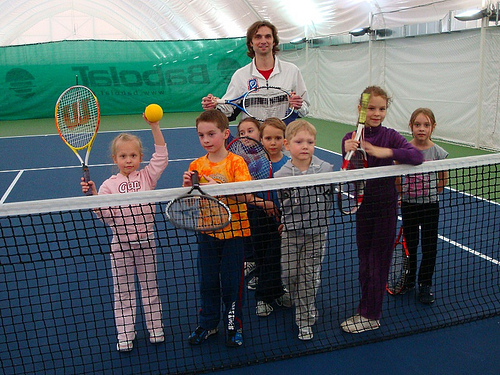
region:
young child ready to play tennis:
[93, 128, 168, 334]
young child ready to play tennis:
[181, 114, 251, 319]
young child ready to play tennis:
[235, 116, 257, 153]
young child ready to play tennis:
[257, 118, 286, 155]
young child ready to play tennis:
[281, 122, 343, 336]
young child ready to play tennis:
[345, 91, 402, 321]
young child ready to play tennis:
[404, 96, 458, 308]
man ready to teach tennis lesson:
[221, 21, 306, 115]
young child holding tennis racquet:
[39, 67, 106, 169]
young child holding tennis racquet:
[170, 183, 234, 243]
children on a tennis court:
[49, 82, 486, 349]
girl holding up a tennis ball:
[49, 85, 170, 190]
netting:
[0, 180, 498, 372]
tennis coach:
[198, 17, 317, 104]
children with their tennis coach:
[51, 17, 450, 355]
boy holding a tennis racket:
[170, 115, 263, 355]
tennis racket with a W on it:
[50, 77, 100, 187]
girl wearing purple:
[343, 78, 419, 336]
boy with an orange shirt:
[181, 106, 253, 244]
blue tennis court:
[0, 129, 492, 373]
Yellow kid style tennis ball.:
[140, 92, 179, 134]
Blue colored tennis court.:
[16, 144, 64, 196]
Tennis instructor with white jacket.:
[231, 23, 318, 120]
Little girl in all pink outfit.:
[97, 134, 164, 348]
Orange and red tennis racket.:
[42, 80, 105, 179]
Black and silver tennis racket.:
[162, 162, 231, 267]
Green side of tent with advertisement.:
[9, 50, 238, 87]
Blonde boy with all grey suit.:
[274, 119, 334, 334]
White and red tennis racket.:
[328, 92, 372, 221]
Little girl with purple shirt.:
[339, 95, 420, 189]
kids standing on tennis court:
[21, 105, 462, 325]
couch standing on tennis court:
[197, 10, 314, 145]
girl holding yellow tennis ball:
[125, 92, 185, 159]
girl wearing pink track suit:
[77, 125, 189, 341]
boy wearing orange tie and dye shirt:
[188, 101, 274, 257]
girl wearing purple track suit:
[345, 82, 424, 333]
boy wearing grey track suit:
[272, 108, 339, 337]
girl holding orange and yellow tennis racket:
[45, 69, 124, 224]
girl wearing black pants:
[385, 98, 460, 338]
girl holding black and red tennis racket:
[377, 174, 430, 321]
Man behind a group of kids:
[201, 19, 311, 119]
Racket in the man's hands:
[216, 87, 295, 120]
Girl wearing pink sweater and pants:
[63, 112, 168, 348]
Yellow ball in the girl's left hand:
[143, 102, 161, 122]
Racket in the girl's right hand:
[54, 83, 99, 196]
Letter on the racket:
[61, 97, 91, 127]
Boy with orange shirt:
[181, 107, 253, 347]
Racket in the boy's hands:
[166, 169, 231, 232]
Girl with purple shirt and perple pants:
[340, 85, 422, 331]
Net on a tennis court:
[2, 152, 499, 372]